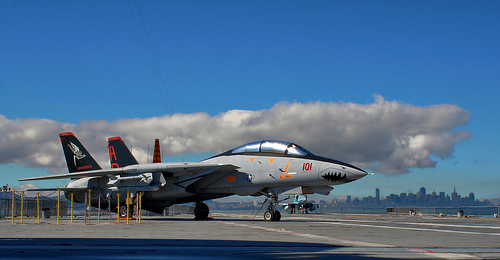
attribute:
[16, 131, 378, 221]
jet — gray, red, black, blue, parked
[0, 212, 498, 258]
landing strip — gray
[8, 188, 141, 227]
poles — yellow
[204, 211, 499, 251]
stripes — white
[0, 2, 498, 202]
sky — blue, clear, cloudy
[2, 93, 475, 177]
cloud — white, gray, huge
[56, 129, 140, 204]
tail — red, white, black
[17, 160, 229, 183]
wing — red, black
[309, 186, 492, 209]
buildings — brown, tall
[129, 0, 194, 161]
cable — overhead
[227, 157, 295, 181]
stickers — orange